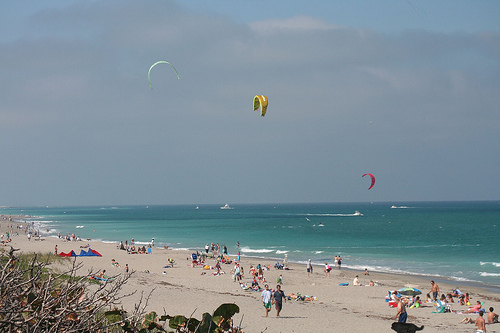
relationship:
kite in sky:
[255, 94, 268, 116] [0, 1, 495, 208]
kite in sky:
[361, 171, 376, 189] [0, 1, 495, 208]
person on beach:
[462, 315, 477, 323] [3, 213, 498, 327]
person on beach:
[275, 286, 285, 315] [3, 213, 498, 327]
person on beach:
[264, 284, 274, 318] [3, 213, 498, 327]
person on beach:
[395, 300, 410, 326] [3, 213, 498, 327]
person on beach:
[354, 275, 364, 287] [3, 213, 498, 327]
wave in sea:
[76, 223, 86, 229] [2, 202, 499, 289]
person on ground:
[462, 315, 477, 323] [0, 212, 499, 329]